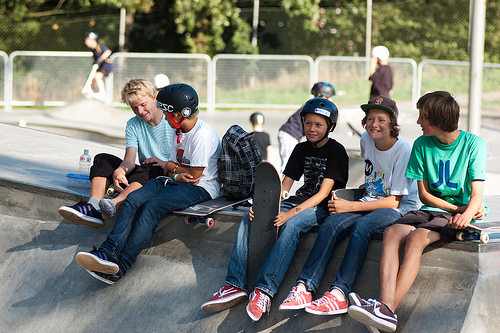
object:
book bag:
[219, 125, 260, 196]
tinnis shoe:
[76, 251, 119, 272]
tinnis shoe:
[58, 198, 105, 228]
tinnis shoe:
[84, 270, 123, 284]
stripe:
[89, 250, 110, 260]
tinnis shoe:
[201, 285, 251, 316]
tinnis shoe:
[247, 286, 270, 321]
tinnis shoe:
[279, 287, 313, 310]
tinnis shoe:
[305, 292, 348, 315]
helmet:
[300, 99, 341, 143]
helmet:
[158, 83, 199, 119]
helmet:
[311, 80, 335, 100]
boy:
[56, 79, 226, 282]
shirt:
[282, 138, 348, 209]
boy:
[350, 92, 488, 330]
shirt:
[408, 129, 488, 218]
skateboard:
[175, 197, 254, 225]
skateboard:
[247, 161, 282, 303]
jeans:
[224, 203, 326, 296]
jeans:
[99, 176, 214, 264]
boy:
[278, 96, 422, 314]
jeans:
[295, 207, 406, 296]